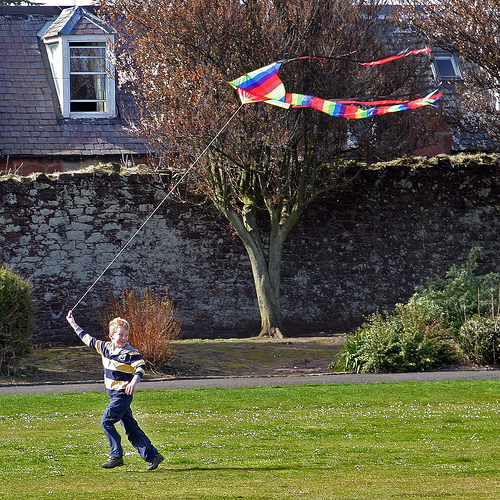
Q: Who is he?
A: Kid.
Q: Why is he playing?
A: Fun.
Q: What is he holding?
A: String.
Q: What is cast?
A: Shadow.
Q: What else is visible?
A: Tree.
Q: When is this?
A: Daytime.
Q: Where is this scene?
A: At a park.